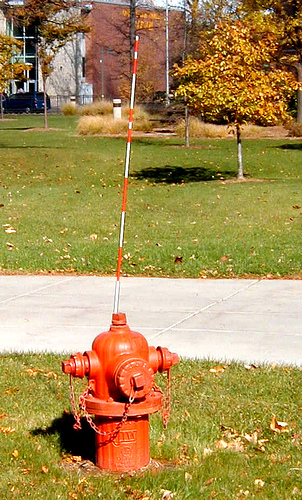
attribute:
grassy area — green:
[134, 191, 301, 242]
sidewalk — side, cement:
[1, 274, 300, 365]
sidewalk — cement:
[5, 278, 298, 343]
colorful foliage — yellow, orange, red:
[168, 18, 299, 124]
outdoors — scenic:
[0, 0, 300, 498]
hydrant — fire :
[40, 317, 183, 474]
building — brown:
[1, 1, 200, 113]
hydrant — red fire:
[60, 311, 181, 473]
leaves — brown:
[115, 148, 227, 192]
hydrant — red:
[45, 313, 181, 480]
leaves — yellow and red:
[199, 419, 242, 458]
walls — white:
[38, 1, 183, 99]